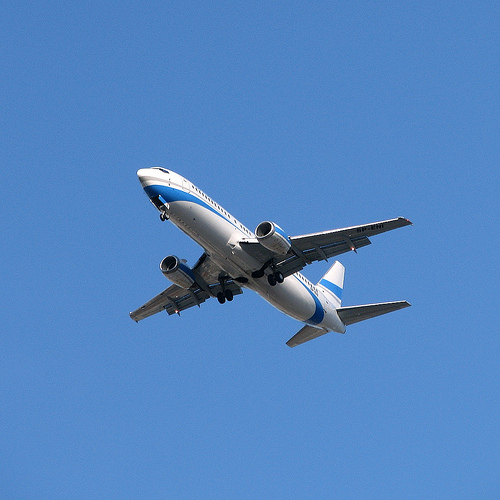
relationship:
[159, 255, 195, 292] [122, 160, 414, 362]
turbines of plane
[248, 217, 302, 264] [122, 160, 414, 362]
turbine of plane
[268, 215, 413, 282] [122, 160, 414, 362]
wing of plane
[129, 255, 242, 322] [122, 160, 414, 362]
wing of plane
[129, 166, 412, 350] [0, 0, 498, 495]
airplane in clear sky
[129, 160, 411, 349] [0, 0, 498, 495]
airplane in clear sky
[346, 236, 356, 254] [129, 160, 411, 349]
light under airplane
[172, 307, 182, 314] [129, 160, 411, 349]
light under airplane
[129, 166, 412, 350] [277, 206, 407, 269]
airplane has wing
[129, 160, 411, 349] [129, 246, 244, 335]
airplane has wing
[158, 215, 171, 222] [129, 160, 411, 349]
wheels are under airplane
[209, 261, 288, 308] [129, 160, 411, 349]
wheels are under airplane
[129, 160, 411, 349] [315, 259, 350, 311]
airplane has tail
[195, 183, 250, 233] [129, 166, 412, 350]
passenger windows on side of airplane